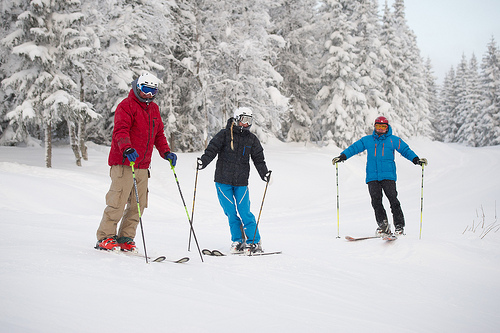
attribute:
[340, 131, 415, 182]
coat — blue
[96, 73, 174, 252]
man — bending, leaning, standing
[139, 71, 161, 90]
helmet — white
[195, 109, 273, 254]
woman — leaning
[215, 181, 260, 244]
pants — bright blue, blue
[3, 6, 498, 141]
trees — snowy, snow-covered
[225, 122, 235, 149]
braid — blonde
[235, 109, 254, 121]
helmet — white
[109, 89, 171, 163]
coat — thick, red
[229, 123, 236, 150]
hair — blonde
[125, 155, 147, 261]
pole — slanted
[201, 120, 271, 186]
coat — black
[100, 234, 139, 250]
ski shoes — red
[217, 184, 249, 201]
stripe — white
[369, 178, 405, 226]
pants — black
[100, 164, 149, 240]
pants — brown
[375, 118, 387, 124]
helmet — red